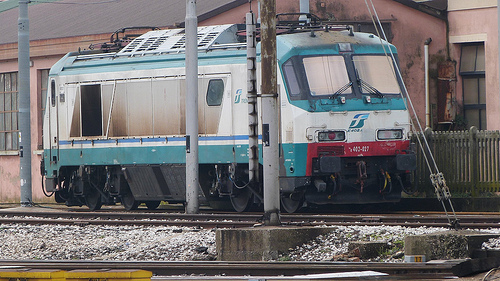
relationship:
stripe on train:
[44, 61, 402, 139] [38, 15, 407, 203]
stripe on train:
[306, 139, 407, 181] [38, 15, 407, 203]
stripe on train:
[54, 49, 250, 72] [38, 15, 407, 203]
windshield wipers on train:
[282, 54, 404, 98] [38, 15, 407, 203]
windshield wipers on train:
[339, 75, 379, 95] [38, 15, 407, 203]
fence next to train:
[402, 128, 497, 207] [38, 15, 407, 203]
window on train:
[77, 88, 108, 135] [38, 15, 407, 203]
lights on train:
[313, 128, 405, 148] [38, 15, 407, 203]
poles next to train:
[181, 1, 286, 219] [38, 15, 407, 203]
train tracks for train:
[4, 198, 498, 241] [38, 15, 407, 203]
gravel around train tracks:
[3, 210, 498, 280] [4, 198, 498, 241]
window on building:
[1, 75, 16, 154] [2, 1, 498, 210]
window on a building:
[35, 71, 49, 157] [2, 1, 498, 210]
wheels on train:
[76, 167, 259, 212] [38, 15, 407, 203]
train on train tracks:
[38, 15, 407, 203] [4, 198, 498, 241]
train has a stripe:
[38, 15, 407, 203] [44, 61, 402, 139]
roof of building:
[3, 1, 240, 29] [2, 1, 498, 210]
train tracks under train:
[4, 198, 498, 241] [38, 15, 407, 203]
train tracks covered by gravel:
[4, 198, 498, 241] [3, 210, 498, 280]